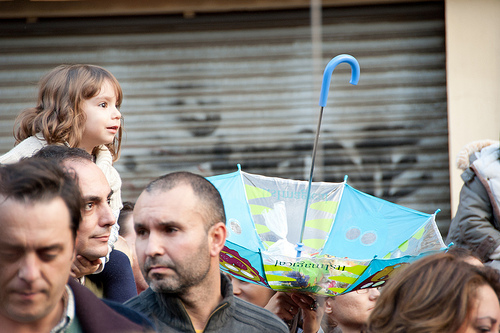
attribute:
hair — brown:
[0, 154, 92, 204]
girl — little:
[0, 62, 127, 277]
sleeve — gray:
[449, 168, 498, 267]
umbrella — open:
[185, 55, 459, 299]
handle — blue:
[319, 53, 360, 108]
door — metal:
[4, 8, 449, 237]